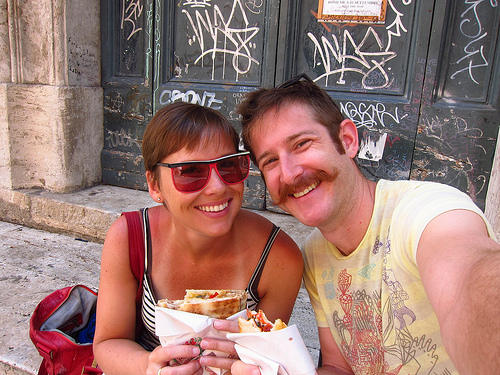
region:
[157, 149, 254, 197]
Red and black glasses on woman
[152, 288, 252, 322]
Food inside of napkin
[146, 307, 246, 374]
Napkin holding food in woman's hands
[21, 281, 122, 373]
Red bag carried by woman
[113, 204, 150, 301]
Strap of the red bag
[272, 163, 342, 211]
Mustache on the man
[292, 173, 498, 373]
Yellow shirt on the man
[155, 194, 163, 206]
Earring on the woman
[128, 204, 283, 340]
White and black shirt on the woman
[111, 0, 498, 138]
Graffiti on the door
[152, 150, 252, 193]
A woman is wearing sunglasses.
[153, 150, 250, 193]
The color of a woman's sunglasses are red.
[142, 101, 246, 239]
A woman is smiling.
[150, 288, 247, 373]
A woman is holding a sandwich.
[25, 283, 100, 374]
A red, gray, and blue bag is sitting next to a woman.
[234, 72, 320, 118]
A man has a pair of sunglasses on his head.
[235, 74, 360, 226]
A man is smiling.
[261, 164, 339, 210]
A man has a twirly mustache.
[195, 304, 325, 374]
A man is holding a sandwich.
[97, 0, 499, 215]
A black wall with graffiti on it is in the background.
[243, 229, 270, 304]
part of a string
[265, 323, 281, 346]
part of a paper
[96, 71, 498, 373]
two people sitting down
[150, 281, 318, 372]
two people holding paninis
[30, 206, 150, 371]
a red purse on woman's shoulder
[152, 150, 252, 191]
a woman with red sunglasses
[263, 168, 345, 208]
a man with a brown mustache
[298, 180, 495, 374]
man wearing a yellow shirt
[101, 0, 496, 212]
graffiti on a black door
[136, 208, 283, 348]
woman wearing a white and black stripe tank top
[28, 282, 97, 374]
an opened red purse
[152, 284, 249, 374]
a panini in a white wrapper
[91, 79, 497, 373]
A couple of smiling people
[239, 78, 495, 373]
A young man with a prominent mustache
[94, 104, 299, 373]
A young woman wearing sunglasses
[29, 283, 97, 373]
A open red bag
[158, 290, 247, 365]
Food wrapped in white paper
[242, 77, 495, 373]
A young man in a yellow shirt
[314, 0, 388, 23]
A sign on a door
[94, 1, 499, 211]
Large black doors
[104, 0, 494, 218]
Large black doors with white graffiti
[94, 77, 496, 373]
A young couple posing for a picture